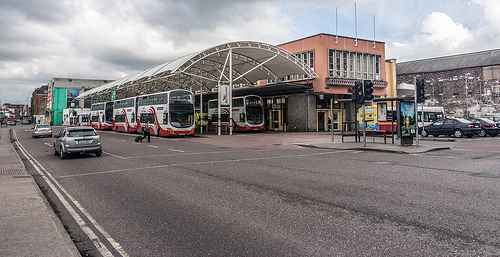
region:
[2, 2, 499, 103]
cloud cover in sky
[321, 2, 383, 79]
three poles on building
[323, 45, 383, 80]
line of tall windows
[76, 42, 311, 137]
busses parked under roof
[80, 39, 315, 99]
long curved gray roof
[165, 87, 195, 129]
front of passenger bus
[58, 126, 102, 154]
back of silver car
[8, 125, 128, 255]
double white lines on asphalt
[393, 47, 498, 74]
long slanted gray roof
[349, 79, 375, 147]
traffic lights on pole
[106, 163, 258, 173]
faint white line across street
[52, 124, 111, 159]
silver car on road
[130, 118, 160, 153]
person walking across road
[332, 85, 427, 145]
bus stop in an island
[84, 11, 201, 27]
large storm clouds gathering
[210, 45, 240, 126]
silver frame on enclosure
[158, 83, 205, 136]
large window on front of bus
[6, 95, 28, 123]
red building in the far distance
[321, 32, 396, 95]
windows in the front of red building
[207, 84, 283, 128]
bus parked under cover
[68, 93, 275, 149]
Busses at bus station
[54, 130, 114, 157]
Silver car driving away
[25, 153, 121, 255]
Double white line on road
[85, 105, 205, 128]
Busses are white and red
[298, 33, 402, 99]
Building is red and tall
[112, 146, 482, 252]
Street is gravel and black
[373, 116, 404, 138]
red object in background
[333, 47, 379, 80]
Tall windows of building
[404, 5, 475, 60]
Big cloud in sky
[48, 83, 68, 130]
Light teal object behind car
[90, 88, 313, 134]
double decker buses at bus station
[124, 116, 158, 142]
person with luggage crossing street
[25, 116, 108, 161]
cars driving in street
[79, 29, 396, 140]
bus station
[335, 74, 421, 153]
bus stop in middle of street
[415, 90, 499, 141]
parked cars in front of bus station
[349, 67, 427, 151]
traffic lights next to bus stop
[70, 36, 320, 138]
protecting roof for buses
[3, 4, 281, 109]
dark clouds looming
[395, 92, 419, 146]
advertisement on bus stop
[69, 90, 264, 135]
rows of red and white buses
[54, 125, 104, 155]
small silver car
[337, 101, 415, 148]
a bus stop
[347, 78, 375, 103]
low mounted traffic lights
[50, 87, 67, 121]
teal corner of a building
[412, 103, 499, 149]
a small aprking lot of cars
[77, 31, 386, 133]
a bus depot with parked buses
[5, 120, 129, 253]
double line painted on street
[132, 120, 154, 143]
person walking across street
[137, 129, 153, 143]
a black colored pair of pants